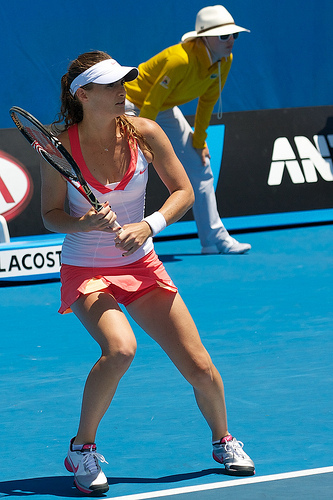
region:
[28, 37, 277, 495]
a woman holding a tennis racket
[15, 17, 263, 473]
the woman is moving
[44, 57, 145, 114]
the woman wearing a visor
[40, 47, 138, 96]
the visor is white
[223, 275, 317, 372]
the court is blue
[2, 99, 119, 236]
the tennis racket is black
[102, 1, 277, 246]
the person leaning forward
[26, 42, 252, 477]
the woman wearing pink shorts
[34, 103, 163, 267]
the woman wearing a white top with pink trim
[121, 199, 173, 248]
the wristband on the arm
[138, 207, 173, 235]
A white wrist band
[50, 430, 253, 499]
A pair of tennis shoes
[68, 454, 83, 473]
A pink nike logo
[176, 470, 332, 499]
White markings on the court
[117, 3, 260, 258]
The person bends over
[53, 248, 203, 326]
A pink tennis skirt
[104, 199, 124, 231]
Her fingernails are painted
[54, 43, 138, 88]
A white sunvisor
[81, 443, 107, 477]
White laces for the shoe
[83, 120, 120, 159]
A silver chain on neck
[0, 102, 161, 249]
Black and red tennis racket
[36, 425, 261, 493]
The person is wearing white, red, and black shoes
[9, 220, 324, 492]
The court is blue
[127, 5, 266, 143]
The person is hunched over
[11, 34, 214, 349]
The woman is holding a tennis racket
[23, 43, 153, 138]
The woman has a white hat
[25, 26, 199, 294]
The woman has a red and white tank top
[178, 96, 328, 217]
The sign is black, blue and white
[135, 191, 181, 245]
The woman is wearing a white arm band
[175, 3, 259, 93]
The person is wearing sunglasses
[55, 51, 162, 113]
tennis player wearing a white visor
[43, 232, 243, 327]
tennis skirt is pink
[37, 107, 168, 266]
player holding racket with two hands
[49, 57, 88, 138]
player's hair is in a ponytail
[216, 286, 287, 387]
tennis court is blue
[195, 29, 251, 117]
string to the hat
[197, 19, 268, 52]
person wearing white sunglasses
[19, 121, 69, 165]
red W on the tennis racket net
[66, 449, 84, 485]
sneaker have a pink nike sign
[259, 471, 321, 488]
white line on the tennis court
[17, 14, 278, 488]
a scene outside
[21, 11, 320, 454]
a scene happening during the day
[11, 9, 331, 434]
on a tennis court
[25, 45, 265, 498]
a tennis player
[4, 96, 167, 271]
a black ratchet in a hand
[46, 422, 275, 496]
pair of white shoes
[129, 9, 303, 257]
a person in background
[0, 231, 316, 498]
a blue tennis court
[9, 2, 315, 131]
a blue barricade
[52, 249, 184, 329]
a pink shirt